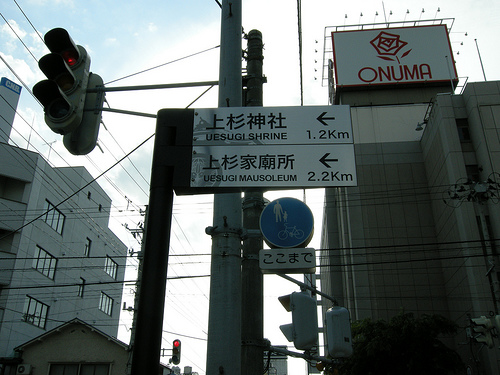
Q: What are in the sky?
A: Clouds.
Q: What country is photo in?
A: Asia.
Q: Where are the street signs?
A: On post.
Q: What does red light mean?
A: To stop.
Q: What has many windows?
A: Building.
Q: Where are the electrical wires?
A: Connected to poles.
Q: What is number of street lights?
A: Two.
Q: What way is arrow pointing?
A: Left.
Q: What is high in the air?
A: Power lines.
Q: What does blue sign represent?
A: Bicycles.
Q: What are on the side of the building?
A: Windows.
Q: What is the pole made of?
A: Metal and wood.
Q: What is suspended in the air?
A: Wire.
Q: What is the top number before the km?
A: 1.2.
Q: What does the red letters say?
A: ONUMA.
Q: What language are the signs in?
A: Japanese.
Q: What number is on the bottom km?
A: 2.2.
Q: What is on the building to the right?
A: Sign.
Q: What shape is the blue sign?
A: Circle.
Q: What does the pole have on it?
A: Signs.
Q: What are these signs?
A: Distance signs.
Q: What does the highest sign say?
A: Onuma.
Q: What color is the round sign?
A: Blue.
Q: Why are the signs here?
A: To inform drivers.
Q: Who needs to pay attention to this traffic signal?
A: Drivers.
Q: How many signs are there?
A: Five.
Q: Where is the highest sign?
A: At the top of the building.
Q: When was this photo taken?
A: During the day.